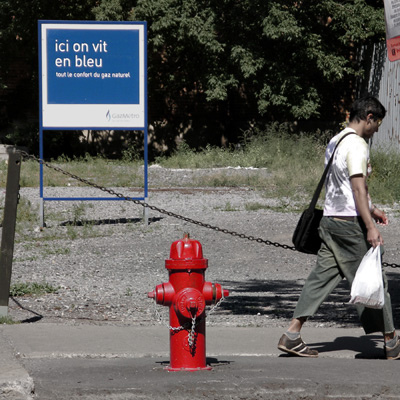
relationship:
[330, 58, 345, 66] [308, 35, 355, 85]
leaves on tree branches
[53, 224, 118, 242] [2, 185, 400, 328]
weeds on driveway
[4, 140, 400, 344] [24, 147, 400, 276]
fence with chain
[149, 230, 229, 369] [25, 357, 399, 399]
fire hydrant on street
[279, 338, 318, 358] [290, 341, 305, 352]
sneaker has stripes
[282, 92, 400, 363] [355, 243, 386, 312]
man holding grocery bag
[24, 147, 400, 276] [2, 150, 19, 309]
chain connected to post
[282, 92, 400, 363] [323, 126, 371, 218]
man wearing shirt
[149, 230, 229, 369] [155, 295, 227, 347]
fire hydrant with attached chain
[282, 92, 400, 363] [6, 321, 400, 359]
man walking on sidewalk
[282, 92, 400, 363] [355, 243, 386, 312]
man carrying grocery bag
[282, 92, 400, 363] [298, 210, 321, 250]
man carrying bag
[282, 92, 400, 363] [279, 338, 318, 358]
man wearing sneaker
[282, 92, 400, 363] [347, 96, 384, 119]
man has hair